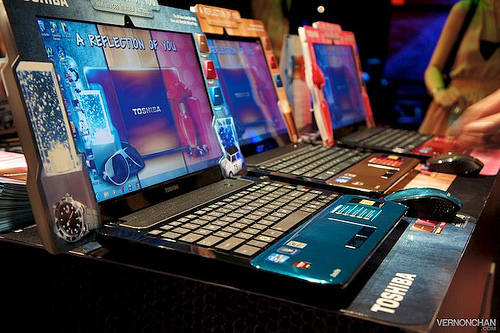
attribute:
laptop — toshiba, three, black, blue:
[0, 1, 411, 300]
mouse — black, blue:
[382, 188, 463, 222]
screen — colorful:
[36, 16, 225, 199]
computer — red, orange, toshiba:
[295, 17, 464, 159]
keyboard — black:
[148, 178, 338, 256]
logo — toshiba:
[368, 270, 417, 316]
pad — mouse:
[353, 205, 474, 321]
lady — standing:
[417, 0, 499, 135]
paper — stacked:
[1, 145, 34, 189]